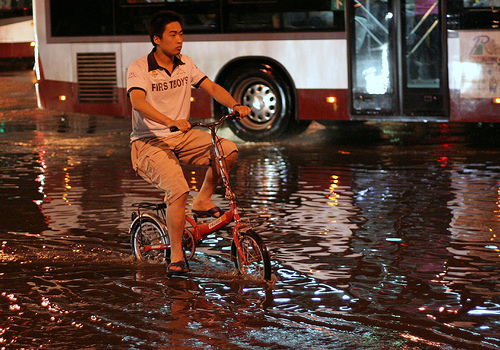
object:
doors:
[347, 0, 405, 122]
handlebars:
[167, 124, 181, 134]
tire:
[219, 61, 294, 144]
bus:
[29, 0, 499, 145]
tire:
[128, 212, 172, 267]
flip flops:
[163, 257, 192, 275]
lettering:
[151, 82, 169, 92]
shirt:
[125, 45, 210, 145]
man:
[123, 10, 251, 275]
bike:
[127, 110, 272, 283]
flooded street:
[0, 69, 499, 349]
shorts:
[128, 127, 239, 207]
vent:
[75, 50, 120, 105]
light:
[57, 92, 69, 103]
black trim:
[188, 73, 207, 89]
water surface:
[0, 71, 499, 349]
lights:
[189, 170, 197, 177]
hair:
[147, 10, 185, 47]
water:
[0, 68, 499, 349]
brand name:
[206, 214, 223, 230]